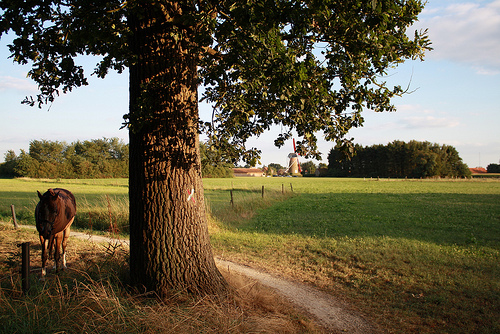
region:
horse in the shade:
[10, 180, 102, 281]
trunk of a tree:
[113, 63, 233, 305]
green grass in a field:
[356, 171, 471, 276]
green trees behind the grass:
[346, 135, 459, 193]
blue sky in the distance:
[415, 65, 491, 115]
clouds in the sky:
[390, 108, 474, 145]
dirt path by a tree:
[259, 273, 333, 310]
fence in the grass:
[225, 177, 297, 209]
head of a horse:
[43, 190, 69, 242]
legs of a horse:
[33, 236, 74, 277]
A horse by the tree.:
[35, 178, 92, 298]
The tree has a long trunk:
[122, 105, 207, 300]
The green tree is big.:
[86, 14, 282, 246]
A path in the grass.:
[221, 250, 331, 330]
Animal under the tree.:
[23, 165, 218, 307]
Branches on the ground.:
[56, 266, 161, 318]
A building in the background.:
[224, 153, 286, 185]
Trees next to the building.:
[305, 132, 466, 187]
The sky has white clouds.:
[400, 16, 477, 126]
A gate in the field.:
[202, 173, 318, 203]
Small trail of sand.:
[242, 252, 336, 319]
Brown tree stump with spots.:
[138, 153, 209, 285]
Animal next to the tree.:
[28, 173, 82, 281]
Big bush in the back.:
[318, 122, 462, 182]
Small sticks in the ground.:
[215, 175, 289, 207]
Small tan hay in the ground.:
[62, 263, 217, 330]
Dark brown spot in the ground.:
[20, 231, 50, 299]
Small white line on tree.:
[182, 171, 203, 213]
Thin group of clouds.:
[437, 1, 488, 66]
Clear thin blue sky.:
[410, 81, 488, 148]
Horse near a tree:
[26, 160, 90, 255]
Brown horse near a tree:
[29, 175, 74, 268]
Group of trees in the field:
[331, 120, 464, 185]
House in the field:
[231, 162, 273, 182]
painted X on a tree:
[181, 184, 202, 212]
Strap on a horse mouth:
[32, 210, 59, 242]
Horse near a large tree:
[36, 175, 89, 275]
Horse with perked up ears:
[30, 187, 74, 243]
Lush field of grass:
[328, 166, 470, 241]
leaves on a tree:
[208, 22, 366, 147]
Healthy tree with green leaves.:
[77, 2, 390, 313]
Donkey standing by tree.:
[26, 186, 80, 273]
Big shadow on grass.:
[261, 182, 496, 265]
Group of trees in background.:
[332, 142, 467, 178]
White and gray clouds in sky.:
[422, 9, 499, 143]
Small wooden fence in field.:
[207, 179, 301, 212]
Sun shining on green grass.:
[207, 172, 487, 202]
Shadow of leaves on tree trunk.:
[140, 18, 200, 190]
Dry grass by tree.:
[75, 293, 260, 327]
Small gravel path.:
[223, 255, 371, 332]